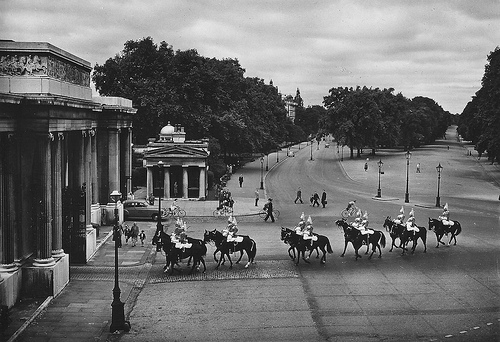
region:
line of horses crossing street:
[153, 205, 480, 275]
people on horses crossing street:
[169, 208, 246, 237]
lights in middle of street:
[370, 149, 448, 201]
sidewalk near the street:
[66, 285, 104, 340]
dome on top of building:
[158, 120, 176, 132]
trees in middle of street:
[331, 81, 441, 148]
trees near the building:
[108, 42, 288, 140]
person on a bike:
[166, 183, 191, 225]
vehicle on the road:
[124, 195, 164, 219]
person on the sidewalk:
[236, 161, 243, 191]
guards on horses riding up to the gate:
[153, 200, 460, 270]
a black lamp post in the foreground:
[110, 191, 130, 330]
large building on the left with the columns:
[2, 40, 133, 313]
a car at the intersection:
[120, 197, 165, 219]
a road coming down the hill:
[263, 138, 496, 336]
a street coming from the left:
[122, 202, 279, 223]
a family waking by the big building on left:
[113, 219, 145, 246]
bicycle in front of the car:
[166, 195, 183, 216]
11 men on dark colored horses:
[157, 203, 462, 267]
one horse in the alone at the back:
[427, 203, 461, 246]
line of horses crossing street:
[142, 194, 466, 275]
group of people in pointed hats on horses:
[153, 197, 465, 277]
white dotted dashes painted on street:
[429, 317, 493, 339]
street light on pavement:
[100, 180, 139, 335]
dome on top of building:
[152, 117, 181, 135]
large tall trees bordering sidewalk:
[96, 33, 306, 170]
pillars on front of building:
[24, 135, 73, 265]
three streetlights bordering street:
[363, 140, 453, 210]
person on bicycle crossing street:
[328, 188, 364, 217]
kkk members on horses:
[202, 209, 264, 272]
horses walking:
[282, 220, 458, 248]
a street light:
[107, 183, 136, 311]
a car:
[128, 195, 153, 218]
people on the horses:
[295, 210, 317, 237]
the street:
[323, 277, 426, 322]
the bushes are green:
[141, 51, 238, 116]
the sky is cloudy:
[296, 21, 399, 65]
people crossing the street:
[309, 186, 335, 209]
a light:
[429, 163, 446, 200]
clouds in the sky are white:
[290, 11, 393, 59]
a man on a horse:
[427, 197, 469, 244]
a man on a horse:
[380, 200, 431, 252]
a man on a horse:
[329, 204, 384, 265]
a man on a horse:
[277, 214, 333, 275]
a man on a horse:
[190, 208, 273, 280]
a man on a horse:
[140, 220, 226, 290]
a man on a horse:
[144, 216, 212, 261]